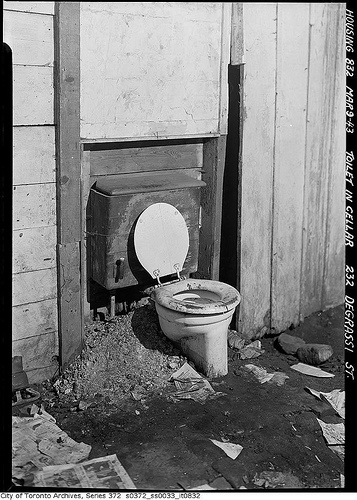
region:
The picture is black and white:
[71, 102, 282, 349]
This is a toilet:
[89, 221, 300, 415]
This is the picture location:
[319, 5, 356, 379]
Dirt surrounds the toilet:
[85, 305, 307, 453]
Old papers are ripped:
[28, 406, 342, 479]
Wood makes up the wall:
[19, 295, 115, 388]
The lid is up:
[104, 196, 286, 331]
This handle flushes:
[98, 225, 178, 339]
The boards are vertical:
[231, 95, 355, 216]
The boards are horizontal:
[22, 124, 95, 380]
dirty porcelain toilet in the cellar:
[87, 175, 240, 379]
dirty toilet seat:
[145, 274, 233, 310]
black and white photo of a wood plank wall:
[244, 2, 326, 301]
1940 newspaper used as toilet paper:
[157, 359, 217, 396]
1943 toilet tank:
[90, 162, 198, 283]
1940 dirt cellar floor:
[153, 398, 306, 459]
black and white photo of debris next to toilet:
[61, 276, 240, 411]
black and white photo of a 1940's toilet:
[130, 199, 244, 378]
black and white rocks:
[271, 331, 335, 369]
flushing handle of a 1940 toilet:
[110, 252, 129, 286]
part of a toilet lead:
[160, 197, 184, 282]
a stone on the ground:
[298, 332, 326, 366]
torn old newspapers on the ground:
[14, 397, 140, 487]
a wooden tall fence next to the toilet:
[253, 49, 343, 324]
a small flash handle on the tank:
[112, 252, 127, 279]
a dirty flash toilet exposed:
[135, 206, 226, 350]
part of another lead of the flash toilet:
[164, 293, 231, 312]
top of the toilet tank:
[107, 162, 204, 199]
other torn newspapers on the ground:
[172, 367, 201, 402]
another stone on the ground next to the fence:
[275, 321, 293, 359]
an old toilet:
[126, 204, 248, 367]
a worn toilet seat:
[160, 276, 237, 311]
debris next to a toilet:
[103, 317, 179, 383]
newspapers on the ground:
[34, 419, 122, 498]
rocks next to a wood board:
[266, 323, 329, 370]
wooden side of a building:
[256, 142, 323, 247]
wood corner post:
[59, 37, 85, 304]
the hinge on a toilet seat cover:
[153, 263, 163, 281]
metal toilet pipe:
[104, 288, 122, 314]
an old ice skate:
[6, 355, 33, 406]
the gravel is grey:
[100, 333, 173, 371]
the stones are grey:
[277, 330, 342, 362]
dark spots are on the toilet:
[165, 286, 244, 312]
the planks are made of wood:
[271, 28, 328, 316]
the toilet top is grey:
[97, 180, 207, 277]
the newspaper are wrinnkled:
[32, 428, 83, 480]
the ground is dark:
[208, 403, 291, 435]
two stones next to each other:
[278, 329, 334, 363]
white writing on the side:
[345, 17, 356, 84]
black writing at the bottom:
[0, 493, 71, 497]